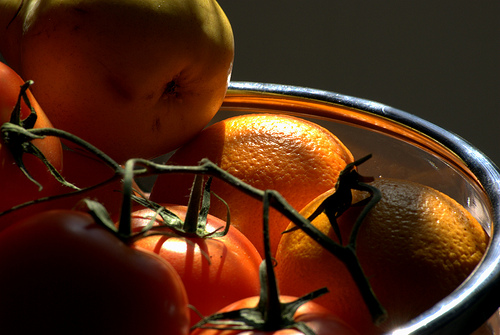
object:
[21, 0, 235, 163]
apple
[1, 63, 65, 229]
tomato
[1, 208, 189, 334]
tomato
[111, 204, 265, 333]
tomato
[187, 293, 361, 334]
tomato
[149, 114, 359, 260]
orange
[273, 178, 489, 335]
orange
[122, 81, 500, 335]
bowl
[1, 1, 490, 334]
produce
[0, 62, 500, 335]
vine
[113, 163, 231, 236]
leaf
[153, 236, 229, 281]
shadow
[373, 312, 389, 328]
tip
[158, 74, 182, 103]
stem